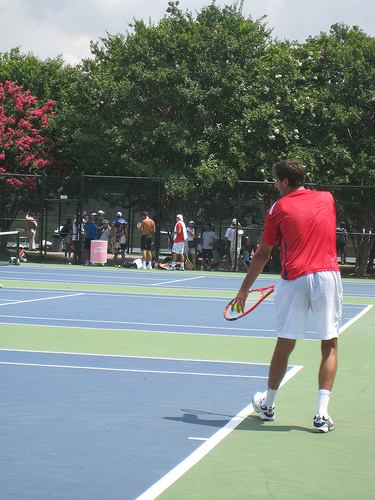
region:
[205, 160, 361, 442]
this is a tennis player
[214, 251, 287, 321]
his hand is holding a racket and a ball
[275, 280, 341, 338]
he is wearing white shorts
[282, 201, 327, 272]
the t shirt is red in color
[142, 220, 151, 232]
the man is bare chested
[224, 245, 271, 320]
the hand is facing the ground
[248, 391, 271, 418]
the left feet is raised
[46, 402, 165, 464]
the pitch is blue in color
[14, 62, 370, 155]
thhe trees are leafy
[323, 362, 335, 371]
the man is light skinned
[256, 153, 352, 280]
A man's torso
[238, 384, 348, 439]
A man wearing white shoes and white socks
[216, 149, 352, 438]
A man playing tennis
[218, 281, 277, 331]
Someone preparing to serve a tennis ball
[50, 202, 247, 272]
Spectators at the edge of a tennis court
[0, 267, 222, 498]
A blue and green tennis court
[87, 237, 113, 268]
A pink barrel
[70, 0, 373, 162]
Tree tops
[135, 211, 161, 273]
A shirtless man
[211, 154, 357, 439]
A man preparing to serve a tennis ball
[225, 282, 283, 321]
Tennis racket that mans holding.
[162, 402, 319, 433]
Shadow of a man and racket.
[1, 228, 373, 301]
Part of a blue and green tennis court.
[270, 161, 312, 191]
Brown haired head of a man.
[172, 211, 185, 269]
Man standing with red shirt on.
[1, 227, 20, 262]
Part of a tennis net.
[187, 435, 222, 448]
White lines on a tennis court.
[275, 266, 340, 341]
White shorts of a man playing tennis.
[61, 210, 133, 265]
Group of people standing around.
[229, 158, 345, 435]
Man getting ready to serve a ball.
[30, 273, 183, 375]
this is a tennis pitch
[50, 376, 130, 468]
the floor is blue in color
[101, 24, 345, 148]
these are some trees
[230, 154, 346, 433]
this is a man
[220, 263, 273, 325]
the man is holding a racket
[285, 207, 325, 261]
this is a t-shirt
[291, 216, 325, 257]
the t-shirt is red in color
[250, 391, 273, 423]
the man's foot is raised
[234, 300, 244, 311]
the tennis ball is green in color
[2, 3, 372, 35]
the blue sky above the trees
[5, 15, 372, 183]
the trees behind the fence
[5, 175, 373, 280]
the fence next to the tennis courts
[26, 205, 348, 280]
the people standing around watching or playing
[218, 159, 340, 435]
the man at the end of the court with the tennis ball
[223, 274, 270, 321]
the red racket the man is holding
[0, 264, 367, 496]
the blue tennis courts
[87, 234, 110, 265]
a pink container next to the fence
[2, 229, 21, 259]
part of a net for the tennis court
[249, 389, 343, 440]
the man's tennis shoes